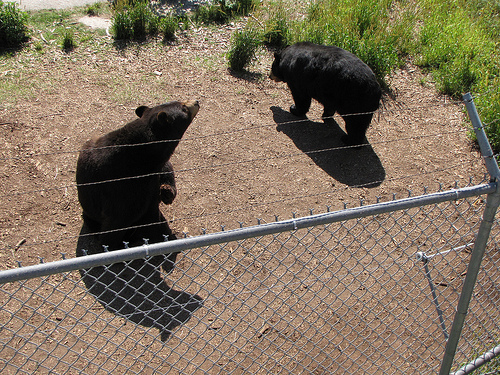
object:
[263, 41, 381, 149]
bear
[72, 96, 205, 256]
bear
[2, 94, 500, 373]
fencing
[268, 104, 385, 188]
shadow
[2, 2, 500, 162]
grass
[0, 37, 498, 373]
soil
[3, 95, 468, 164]
wire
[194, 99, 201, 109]
snout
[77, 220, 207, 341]
shadow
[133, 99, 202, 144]
head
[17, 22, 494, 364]
forest